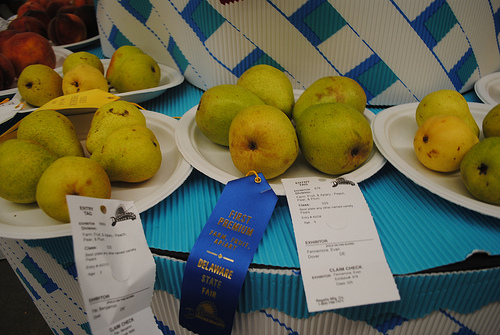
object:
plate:
[173, 88, 388, 196]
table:
[0, 43, 500, 335]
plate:
[0, 109, 193, 240]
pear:
[34, 155, 111, 223]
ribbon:
[177, 171, 279, 334]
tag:
[65, 195, 165, 334]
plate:
[0, 46, 77, 95]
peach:
[3, 32, 53, 80]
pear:
[228, 103, 300, 180]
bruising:
[108, 107, 130, 117]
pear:
[86, 99, 146, 154]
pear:
[412, 115, 479, 173]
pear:
[194, 84, 268, 147]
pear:
[235, 63, 294, 117]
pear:
[15, 110, 84, 159]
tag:
[281, 176, 400, 313]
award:
[35, 88, 124, 110]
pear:
[90, 123, 162, 183]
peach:
[46, 13, 87, 46]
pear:
[0, 138, 61, 205]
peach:
[7, 15, 47, 39]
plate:
[369, 99, 499, 218]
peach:
[22, 8, 48, 23]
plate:
[0, 15, 100, 49]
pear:
[415, 89, 481, 140]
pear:
[110, 53, 161, 93]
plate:
[16, 58, 184, 113]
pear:
[296, 102, 373, 175]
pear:
[291, 76, 368, 124]